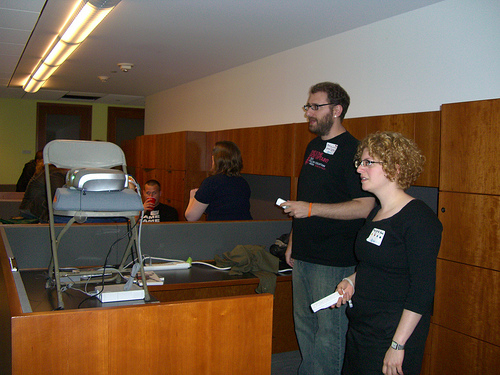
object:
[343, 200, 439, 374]
clothing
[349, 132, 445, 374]
woman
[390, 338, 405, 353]
watch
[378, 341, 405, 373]
hand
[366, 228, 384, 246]
name tag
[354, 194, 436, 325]
vest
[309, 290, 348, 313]
controller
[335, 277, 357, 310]
hand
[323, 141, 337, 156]
name tag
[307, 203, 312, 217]
wristband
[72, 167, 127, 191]
projector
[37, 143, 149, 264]
chair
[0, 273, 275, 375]
desk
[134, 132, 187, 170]
cabinets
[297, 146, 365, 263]
shirt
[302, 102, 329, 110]
glasses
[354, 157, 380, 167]
glasses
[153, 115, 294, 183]
wall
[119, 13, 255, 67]
ceiling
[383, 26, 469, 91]
wall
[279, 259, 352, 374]
jeans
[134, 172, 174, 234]
man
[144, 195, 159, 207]
cup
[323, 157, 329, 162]
words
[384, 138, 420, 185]
hair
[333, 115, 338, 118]
earring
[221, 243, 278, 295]
garment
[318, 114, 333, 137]
beard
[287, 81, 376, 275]
gamers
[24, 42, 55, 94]
light fixture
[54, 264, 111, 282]
surge protector